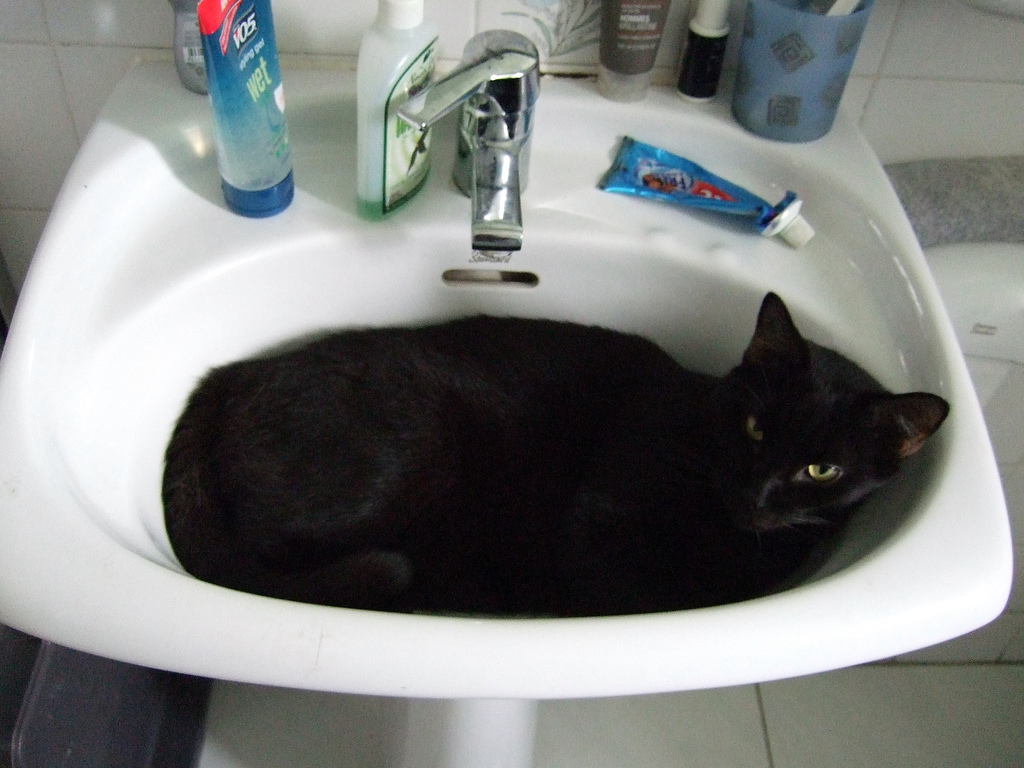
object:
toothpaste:
[595, 134, 816, 252]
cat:
[162, 292, 948, 618]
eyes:
[808, 458, 844, 483]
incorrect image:
[325, 599, 481, 764]